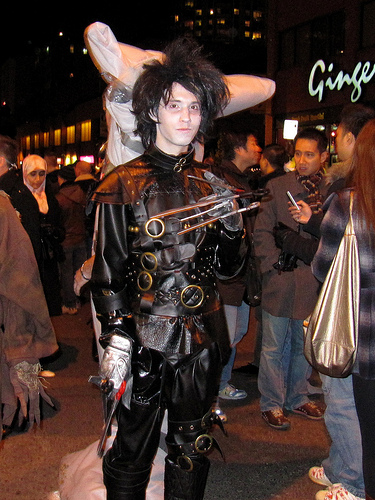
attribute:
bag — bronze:
[303, 189, 360, 379]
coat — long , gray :
[252, 170, 330, 320]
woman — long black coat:
[14, 150, 83, 384]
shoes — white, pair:
[312, 482, 361, 496]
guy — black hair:
[74, 45, 294, 499]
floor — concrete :
[27, 440, 52, 487]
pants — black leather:
[82, 337, 235, 498]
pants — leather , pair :
[96, 334, 228, 497]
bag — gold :
[290, 212, 359, 362]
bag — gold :
[288, 200, 363, 377]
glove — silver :
[90, 334, 137, 404]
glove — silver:
[97, 334, 133, 411]